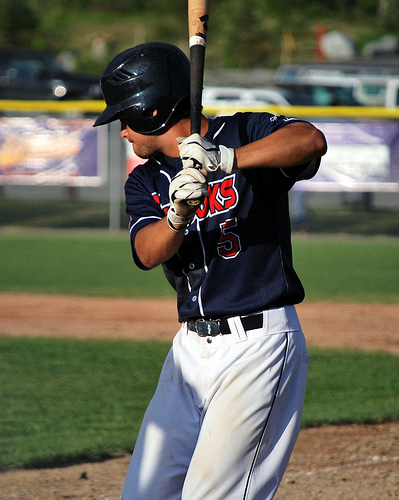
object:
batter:
[84, 33, 325, 499]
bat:
[179, 0, 213, 211]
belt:
[180, 313, 267, 335]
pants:
[121, 316, 312, 498]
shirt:
[122, 108, 326, 311]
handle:
[183, 46, 210, 178]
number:
[218, 216, 242, 261]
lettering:
[148, 176, 243, 259]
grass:
[0, 222, 397, 468]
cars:
[1, 57, 87, 97]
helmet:
[93, 38, 200, 136]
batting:
[83, 0, 351, 278]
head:
[103, 38, 192, 161]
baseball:
[84, 0, 343, 500]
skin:
[98, 97, 324, 263]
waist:
[171, 278, 313, 364]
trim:
[125, 116, 312, 316]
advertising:
[2, 113, 397, 190]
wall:
[2, 100, 392, 230]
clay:
[2, 294, 397, 346]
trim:
[243, 332, 300, 498]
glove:
[166, 171, 208, 226]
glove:
[176, 134, 235, 176]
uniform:
[122, 111, 306, 500]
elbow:
[292, 117, 327, 161]